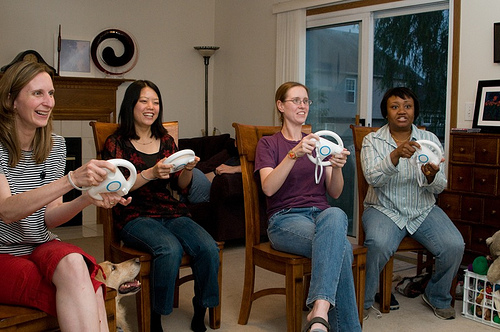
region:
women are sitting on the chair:
[10, 36, 492, 330]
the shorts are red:
[2, 229, 124, 324]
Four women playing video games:
[1, 60, 464, 330]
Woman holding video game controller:
[355, 88, 462, 318]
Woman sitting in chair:
[226, 78, 358, 330]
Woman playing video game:
[227, 74, 359, 330]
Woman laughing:
[1, 52, 116, 329]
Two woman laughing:
[0, 49, 223, 330]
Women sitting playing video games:
[0, 62, 470, 330]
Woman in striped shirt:
[0, 60, 108, 330]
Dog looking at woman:
[85, 70, 220, 330]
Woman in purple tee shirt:
[231, 78, 363, 330]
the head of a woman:
[260, 66, 341, 161]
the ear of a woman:
[271, 89, 286, 113]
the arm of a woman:
[244, 119, 355, 224]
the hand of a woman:
[288, 122, 332, 180]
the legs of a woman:
[278, 178, 408, 290]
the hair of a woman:
[102, 58, 184, 145]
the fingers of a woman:
[151, 153, 179, 198]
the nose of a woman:
[140, 98, 158, 123]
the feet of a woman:
[382, 276, 483, 320]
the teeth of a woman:
[375, 82, 449, 149]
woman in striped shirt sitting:
[355, 75, 470, 321]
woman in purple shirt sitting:
[241, 72, 362, 327]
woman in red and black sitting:
[96, 68, 236, 330]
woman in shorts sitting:
[1, 48, 136, 330]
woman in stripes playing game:
[346, 73, 466, 321]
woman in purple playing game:
[252, 67, 363, 330]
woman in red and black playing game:
[91, 63, 226, 329]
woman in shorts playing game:
[0, 56, 112, 330]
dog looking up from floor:
[89, 247, 146, 329]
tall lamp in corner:
[193, 37, 215, 142]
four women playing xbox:
[8, 54, 461, 329]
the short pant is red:
[0, 240, 97, 305]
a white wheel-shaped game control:
[305, 128, 347, 167]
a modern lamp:
[195, 40, 215, 132]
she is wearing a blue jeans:
[137, 217, 221, 330]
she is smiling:
[118, 80, 215, 304]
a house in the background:
[307, 22, 424, 122]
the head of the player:
[275, 82, 310, 130]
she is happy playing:
[2, 62, 124, 294]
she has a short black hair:
[378, 88, 421, 123]